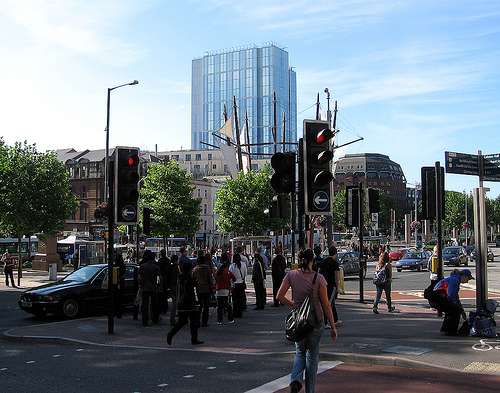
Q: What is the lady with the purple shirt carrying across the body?
A: A purse.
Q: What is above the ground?
A: The sky.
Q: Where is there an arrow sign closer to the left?
A: Under the traffic light.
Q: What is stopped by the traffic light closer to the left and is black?
A: A car.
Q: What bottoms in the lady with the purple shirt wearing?
A: Jeans.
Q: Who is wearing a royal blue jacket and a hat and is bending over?
A: Lady to the far right.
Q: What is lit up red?
A: Traffic lights.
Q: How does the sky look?
A: Blue with wispy clouds.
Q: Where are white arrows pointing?
A: To the left.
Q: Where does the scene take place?
A: Near a city street.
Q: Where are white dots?
A: On the ground.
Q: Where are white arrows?
A: On round signs.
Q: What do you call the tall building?
A: Skyscraper.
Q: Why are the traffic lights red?
A: To stop traffic.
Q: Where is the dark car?
A: Behind the traffic light.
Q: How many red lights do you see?
A: 2.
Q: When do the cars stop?
A: On a red light.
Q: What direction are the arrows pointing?
A: Left.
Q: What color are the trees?
A: Green.